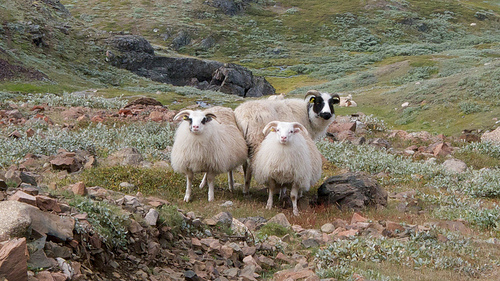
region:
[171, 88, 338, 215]
Three wooly sheep on a mountainside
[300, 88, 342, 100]
The horns on the head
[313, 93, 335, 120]
Black and white head of a sheep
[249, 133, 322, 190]
White fluffy wool on the sheep's body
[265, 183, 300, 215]
Short legs of the sheep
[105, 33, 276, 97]
A Black big rock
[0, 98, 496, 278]
Ground full of brown stones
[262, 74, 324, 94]
A patch of short grass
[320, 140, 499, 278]
Some of the bushes on the ground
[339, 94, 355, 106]
One sheep sitting down at a distance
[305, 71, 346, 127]
head of a sheep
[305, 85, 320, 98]
ear of a sheep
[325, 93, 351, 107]
ear of a sheep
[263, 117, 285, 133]
ear of a sheep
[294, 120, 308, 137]
ear of a sheep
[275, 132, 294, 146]
mouth of a sheep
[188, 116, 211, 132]
mouth of a sheep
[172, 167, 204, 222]
leg of a sheep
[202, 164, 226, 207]
leg of a sheep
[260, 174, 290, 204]
leg of a sheep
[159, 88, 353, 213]
Three mountain goats on hill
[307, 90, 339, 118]
Black and white face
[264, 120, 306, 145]
White head on mountain goat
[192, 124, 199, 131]
Pink nose on mountain goat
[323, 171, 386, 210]
Dark gray rock on ground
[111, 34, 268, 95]
Large dark gray rock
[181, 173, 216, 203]
Front legs on mountain goat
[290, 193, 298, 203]
Brown spot on mountain goat's knee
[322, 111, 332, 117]
Black nose on mountain goat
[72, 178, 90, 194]
Small tan rock on ground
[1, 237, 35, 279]
rock stuck in ground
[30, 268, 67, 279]
rock stuck in ground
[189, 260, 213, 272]
rock stuck in ground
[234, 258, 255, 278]
rock stuck in ground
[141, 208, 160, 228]
rock stuck in ground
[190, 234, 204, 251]
rock stuck in ground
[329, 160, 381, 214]
rock stuck in ground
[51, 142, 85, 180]
rock stuck in ground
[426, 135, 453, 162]
rock stuck in ground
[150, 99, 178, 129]
rock stuck in ground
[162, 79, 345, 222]
the goats beside the rocks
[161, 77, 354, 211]
the three goats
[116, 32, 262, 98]
the large rocks behind the goats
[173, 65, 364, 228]
the goats are shaggy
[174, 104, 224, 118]
horns on the goat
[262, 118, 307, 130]
horns on the goat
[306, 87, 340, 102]
horns on the goat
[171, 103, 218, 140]
head of the goat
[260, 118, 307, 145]
head of the goat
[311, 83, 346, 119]
head of the goat